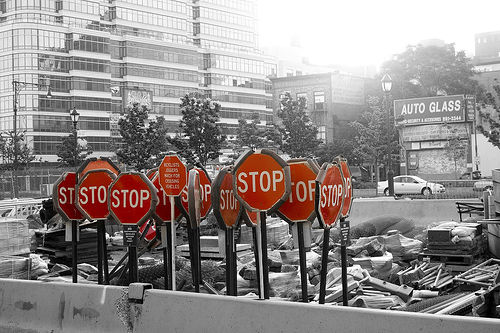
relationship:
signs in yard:
[119, 149, 333, 254] [0, 0, 498, 329]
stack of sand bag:
[423, 220, 489, 263] [451, 230, 475, 242]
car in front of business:
[374, 172, 447, 199] [389, 89, 475, 178]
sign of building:
[330, 73, 366, 106] [3, 1, 273, 198]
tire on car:
[419, 186, 434, 196] [374, 172, 447, 199]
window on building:
[37, 28, 70, 60] [107, 4, 271, 109]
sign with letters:
[229, 147, 290, 211] [237, 171, 282, 191]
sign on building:
[325, 64, 373, 111] [261, 63, 383, 194]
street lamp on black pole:
[382, 76, 391, 94] [386, 95, 394, 194]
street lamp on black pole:
[67, 106, 79, 123] [72, 123, 77, 158]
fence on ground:
[121, 253, 219, 287] [4, 194, 496, 315]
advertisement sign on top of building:
[392, 93, 468, 127] [384, 80, 488, 193]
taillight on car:
[371, 180, 384, 190] [373, 164, 444, 196]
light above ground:
[64, 104, 89, 129] [0, 181, 500, 333]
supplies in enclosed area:
[5, 164, 492, 304] [7, 150, 498, 321]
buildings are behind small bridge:
[1, 2, 390, 186] [0, 203, 492, 311]